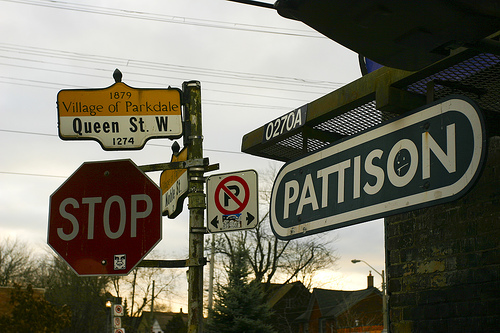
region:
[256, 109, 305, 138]
WHITE NUMBERS ON THE BUILDING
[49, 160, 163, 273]
RED STOP SIGN ON THE POLE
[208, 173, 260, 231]
NO PARKING SIGN ON THE POLE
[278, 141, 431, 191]
STREET SIGN ON THE SIDE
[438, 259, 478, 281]
BUILDING MADE OUT OF BRICKS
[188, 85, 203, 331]
POLE MADE OUT OF MEDAL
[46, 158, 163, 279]
a red sign with white writing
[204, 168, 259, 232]
a small square white sign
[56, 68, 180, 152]
a yellow and white sign with black writing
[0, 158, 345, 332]
trees with green leaves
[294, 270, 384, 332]
a red brick building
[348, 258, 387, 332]
a street light on a metal pole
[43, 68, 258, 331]
signs on a metal pole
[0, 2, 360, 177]
over head electric lines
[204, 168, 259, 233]
a square no parking sign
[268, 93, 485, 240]
a green and white colored sign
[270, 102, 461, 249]
a sign says PATTISON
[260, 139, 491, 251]
a sign says PATTISON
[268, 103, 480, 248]
a sign says PATTISON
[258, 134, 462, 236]
a sign says PATTISON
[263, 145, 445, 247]
a sign says PATTISON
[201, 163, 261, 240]
a No Parking sign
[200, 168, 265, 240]
a No Parking sign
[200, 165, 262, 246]
a No Parking sign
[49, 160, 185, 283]
a red STOP sign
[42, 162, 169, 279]
a red STOP sign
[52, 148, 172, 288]
a red STOP sign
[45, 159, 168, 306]
a red STOP sign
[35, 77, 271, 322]
street signs attached to a pole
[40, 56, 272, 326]
street signs attached to a pole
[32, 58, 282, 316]
street signs attached to a pole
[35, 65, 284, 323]
street signs attached to a pole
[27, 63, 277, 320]
street signs attached to a pole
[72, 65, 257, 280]
sign on a pole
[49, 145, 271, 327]
a sign on pole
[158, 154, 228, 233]
sign on a pole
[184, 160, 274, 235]
sign on a pole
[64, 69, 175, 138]
a sign on a metla pole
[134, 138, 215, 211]
a sign on a metal pole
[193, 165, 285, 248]
a sign on a metal pole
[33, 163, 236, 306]
a sign on a metal pole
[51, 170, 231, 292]
a stop sign on pole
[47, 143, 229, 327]
a sign on a pole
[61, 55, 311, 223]
a sign on a pole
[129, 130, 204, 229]
a sign on a pole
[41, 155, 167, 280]
red and white stop sign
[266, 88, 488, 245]
green and white sign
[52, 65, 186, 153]
yellow and white street sign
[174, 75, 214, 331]
metal street sign support pole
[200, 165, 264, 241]
no parking red, white and black traffic sign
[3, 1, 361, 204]
black power lines hanging in sky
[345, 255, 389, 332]
street light in air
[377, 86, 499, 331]
brick wall behind green and white sign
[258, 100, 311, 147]
black and white number sign on side of metal bar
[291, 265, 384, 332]
brick house in front of street light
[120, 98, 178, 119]
the village is Parkdale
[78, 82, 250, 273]
signs on the post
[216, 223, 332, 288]
the trees are bare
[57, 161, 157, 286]
the sign is red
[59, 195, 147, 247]
stop is on the sign